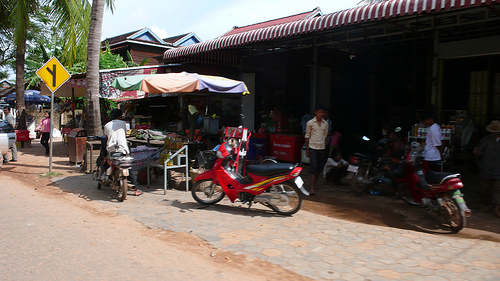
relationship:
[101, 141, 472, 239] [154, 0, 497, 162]
motorcycles front of markets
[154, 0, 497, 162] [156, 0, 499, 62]
produce stand cover with fabric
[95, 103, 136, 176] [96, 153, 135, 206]
person on motorbike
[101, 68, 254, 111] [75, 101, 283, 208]
panel on side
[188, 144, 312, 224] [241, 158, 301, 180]
scooter has black seat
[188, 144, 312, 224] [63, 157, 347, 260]
scooter in center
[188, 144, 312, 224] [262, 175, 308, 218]
scooter has back tire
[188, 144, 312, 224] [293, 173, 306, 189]
scooter has plate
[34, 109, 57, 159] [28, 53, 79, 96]
"person behind y sign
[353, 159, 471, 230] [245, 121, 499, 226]
motorcycles on right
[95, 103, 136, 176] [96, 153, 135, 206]
man on scooter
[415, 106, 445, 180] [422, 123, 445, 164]
man wears shirts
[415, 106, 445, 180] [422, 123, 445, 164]
person wears shirts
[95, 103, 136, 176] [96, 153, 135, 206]
person ribs motor bike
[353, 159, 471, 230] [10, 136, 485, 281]
motorcycles parked on street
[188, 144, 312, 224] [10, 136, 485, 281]
motorcycle parked on road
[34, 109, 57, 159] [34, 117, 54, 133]
person wears pink shirt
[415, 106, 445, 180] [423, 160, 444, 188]
person wears black pants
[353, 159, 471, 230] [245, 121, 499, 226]
motorcycles parked on side street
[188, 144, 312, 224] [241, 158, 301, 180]
motorcycle has black sit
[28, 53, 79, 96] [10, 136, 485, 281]
sign on street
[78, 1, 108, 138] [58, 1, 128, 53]
trunk of tree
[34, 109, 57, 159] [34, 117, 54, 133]
woman wears pink sweter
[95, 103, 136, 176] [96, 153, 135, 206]
person driving bike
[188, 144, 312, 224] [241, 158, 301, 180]
motorcycle sit black